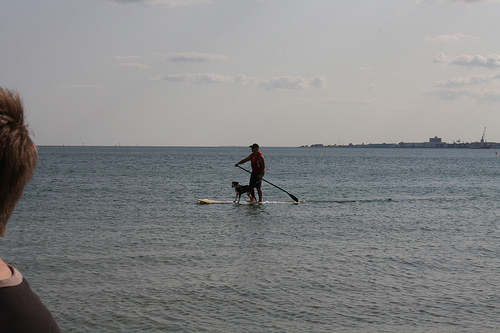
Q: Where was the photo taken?
A: It was taken at the beach.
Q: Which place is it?
A: It is a beach.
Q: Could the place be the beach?
A: Yes, it is the beach.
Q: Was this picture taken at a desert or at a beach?
A: It was taken at a beach.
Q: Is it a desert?
A: No, it is a beach.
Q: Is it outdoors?
A: Yes, it is outdoors.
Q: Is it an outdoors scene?
A: Yes, it is outdoors.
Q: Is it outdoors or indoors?
A: It is outdoors.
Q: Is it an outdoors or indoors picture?
A: It is outdoors.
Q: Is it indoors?
A: No, it is outdoors.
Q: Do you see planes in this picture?
A: No, there are no planes.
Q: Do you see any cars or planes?
A: No, there are no planes or cars.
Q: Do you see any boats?
A: No, there are no boats.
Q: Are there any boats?
A: No, there are no boats.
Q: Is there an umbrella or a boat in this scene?
A: No, there are no boats or umbrellas.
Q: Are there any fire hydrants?
A: No, there are no fire hydrants.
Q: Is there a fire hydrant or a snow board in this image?
A: No, there are no fire hydrants or snowboards.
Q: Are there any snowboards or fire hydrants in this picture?
A: No, there are no fire hydrants or snowboards.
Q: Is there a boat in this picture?
A: No, there are no boats.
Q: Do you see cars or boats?
A: No, there are no boats or cars.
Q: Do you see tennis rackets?
A: No, there are no tennis rackets.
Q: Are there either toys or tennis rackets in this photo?
A: No, there are no tennis rackets or toys.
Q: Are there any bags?
A: No, there are no bags.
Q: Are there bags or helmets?
A: No, there are no bags or helmets.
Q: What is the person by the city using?
A: The person is using a paddle.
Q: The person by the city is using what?
A: The person is using a paddle.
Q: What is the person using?
A: The person is using a paddle.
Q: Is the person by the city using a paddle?
A: Yes, the person is using a paddle.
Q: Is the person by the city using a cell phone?
A: No, the person is using a paddle.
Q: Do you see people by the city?
A: Yes, there is a person by the city.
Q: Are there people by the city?
A: Yes, there is a person by the city.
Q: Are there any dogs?
A: Yes, there is a dog.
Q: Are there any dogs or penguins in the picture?
A: Yes, there is a dog.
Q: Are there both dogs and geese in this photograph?
A: No, there is a dog but no geese.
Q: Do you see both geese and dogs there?
A: No, there is a dog but no geese.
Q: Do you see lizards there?
A: No, there are no lizards.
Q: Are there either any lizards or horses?
A: No, there are no lizards or horses.